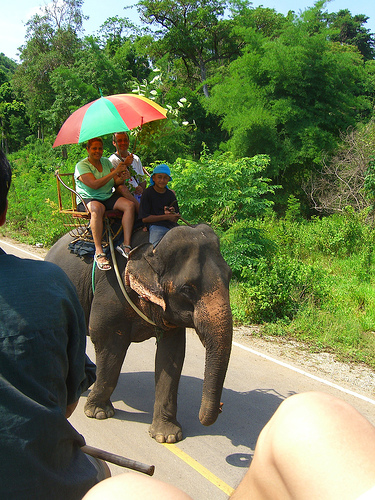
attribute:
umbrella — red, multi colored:
[41, 90, 179, 148]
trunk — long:
[196, 285, 241, 429]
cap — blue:
[149, 163, 177, 187]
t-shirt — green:
[70, 159, 119, 199]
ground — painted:
[0, 237, 374, 499]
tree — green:
[200, 17, 375, 168]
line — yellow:
[159, 432, 249, 499]